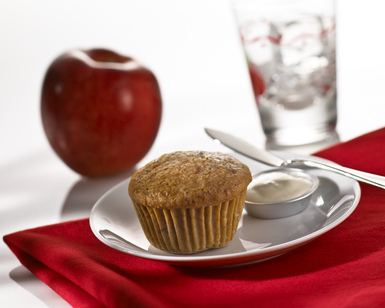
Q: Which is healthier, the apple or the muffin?
A: The apple is healthier than the muffin.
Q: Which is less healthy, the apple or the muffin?
A: The muffin is less healthy than the apple.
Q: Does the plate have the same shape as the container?
A: Yes, both the plate and the container are round.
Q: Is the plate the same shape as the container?
A: Yes, both the plate and the container are round.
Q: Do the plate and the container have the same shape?
A: Yes, both the plate and the container are round.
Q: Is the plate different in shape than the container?
A: No, both the plate and the container are round.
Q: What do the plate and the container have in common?
A: The shape, both the plate and the container are round.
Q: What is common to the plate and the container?
A: The shape, both the plate and the container are round.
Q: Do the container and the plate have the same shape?
A: Yes, both the container and the plate are round.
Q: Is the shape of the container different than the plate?
A: No, both the container and the plate are round.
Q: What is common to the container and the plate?
A: The shape, both the container and the plate are round.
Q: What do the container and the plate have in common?
A: The shape, both the container and the plate are round.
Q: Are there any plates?
A: Yes, there is a plate.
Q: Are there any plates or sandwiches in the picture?
A: Yes, there is a plate.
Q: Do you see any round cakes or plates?
A: Yes, there is a round plate.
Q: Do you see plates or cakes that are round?
A: Yes, the plate is round.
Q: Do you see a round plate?
A: Yes, there is a round plate.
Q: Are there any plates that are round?
A: Yes, there is a plate that is round.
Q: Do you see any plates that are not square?
A: Yes, there is a round plate.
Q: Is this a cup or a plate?
A: This is a plate.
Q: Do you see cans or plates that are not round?
A: No, there is a plate but it is round.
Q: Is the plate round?
A: Yes, the plate is round.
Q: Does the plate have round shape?
A: Yes, the plate is round.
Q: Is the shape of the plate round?
A: Yes, the plate is round.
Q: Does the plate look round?
A: Yes, the plate is round.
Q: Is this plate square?
A: No, the plate is round.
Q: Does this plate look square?
A: No, the plate is round.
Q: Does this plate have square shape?
A: No, the plate is round.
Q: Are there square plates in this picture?
A: No, there is a plate but it is round.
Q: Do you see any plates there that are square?
A: No, there is a plate but it is round.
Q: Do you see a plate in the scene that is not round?
A: No, there is a plate but it is round.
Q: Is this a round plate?
A: Yes, this is a round plate.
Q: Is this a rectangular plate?
A: No, this is a round plate.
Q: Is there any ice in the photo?
A: Yes, there is ice.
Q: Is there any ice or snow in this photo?
A: Yes, there is ice.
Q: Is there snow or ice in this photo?
A: Yes, there is ice.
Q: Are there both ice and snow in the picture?
A: No, there is ice but no snow.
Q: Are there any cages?
A: No, there are no cages.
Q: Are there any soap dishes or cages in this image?
A: No, there are no cages or soap dishes.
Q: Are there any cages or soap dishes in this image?
A: No, there are no cages or soap dishes.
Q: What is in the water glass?
A: The ice is in the water glass.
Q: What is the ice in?
A: The ice is in the water glass.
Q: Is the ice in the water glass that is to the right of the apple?
A: Yes, the ice is in the water glass.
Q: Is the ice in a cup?
A: No, the ice is in the water glass.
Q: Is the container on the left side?
A: No, the container is on the right of the image.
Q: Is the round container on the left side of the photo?
A: No, the container is on the right of the image.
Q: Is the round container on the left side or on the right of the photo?
A: The container is on the right of the image.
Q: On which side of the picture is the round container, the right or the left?
A: The container is on the right of the image.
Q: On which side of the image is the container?
A: The container is on the right of the image.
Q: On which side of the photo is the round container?
A: The container is on the right of the image.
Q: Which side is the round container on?
A: The container is on the right of the image.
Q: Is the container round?
A: Yes, the container is round.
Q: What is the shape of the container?
A: The container is round.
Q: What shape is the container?
A: The container is round.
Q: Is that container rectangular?
A: No, the container is round.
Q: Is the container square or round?
A: The container is round.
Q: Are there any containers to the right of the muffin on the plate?
A: Yes, there is a container to the right of the muffin.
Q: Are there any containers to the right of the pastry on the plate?
A: Yes, there is a container to the right of the muffin.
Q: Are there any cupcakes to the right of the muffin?
A: No, there is a container to the right of the muffin.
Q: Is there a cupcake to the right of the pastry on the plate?
A: No, there is a container to the right of the muffin.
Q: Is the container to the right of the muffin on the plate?
A: Yes, the container is to the right of the muffin.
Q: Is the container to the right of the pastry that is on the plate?
A: Yes, the container is to the right of the muffin.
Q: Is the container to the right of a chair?
A: No, the container is to the right of the muffin.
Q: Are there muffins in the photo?
A: Yes, there is a muffin.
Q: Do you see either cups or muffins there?
A: Yes, there is a muffin.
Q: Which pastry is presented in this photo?
A: The pastry is a muffin.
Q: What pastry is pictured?
A: The pastry is a muffin.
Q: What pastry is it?
A: The pastry is a muffin.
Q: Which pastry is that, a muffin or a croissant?
A: This is a muffin.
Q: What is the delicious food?
A: The food is a muffin.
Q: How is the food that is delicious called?
A: The food is a muffin.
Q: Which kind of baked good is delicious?
A: The baked good is a muffin.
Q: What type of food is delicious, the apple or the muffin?
A: The muffin is delicious.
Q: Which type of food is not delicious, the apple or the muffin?
A: The apple is not delicious.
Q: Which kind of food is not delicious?
A: The food is an apple.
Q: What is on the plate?
A: The muffin is on the plate.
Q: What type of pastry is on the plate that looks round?
A: The pastry is a muffin.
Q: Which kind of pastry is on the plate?
A: The pastry is a muffin.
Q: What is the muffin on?
A: The muffin is on the plate.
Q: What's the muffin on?
A: The muffin is on the plate.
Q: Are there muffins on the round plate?
A: Yes, there is a muffin on the plate.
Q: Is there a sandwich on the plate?
A: No, there is a muffin on the plate.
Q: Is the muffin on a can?
A: No, the muffin is on the plate.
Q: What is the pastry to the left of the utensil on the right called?
A: The pastry is a muffin.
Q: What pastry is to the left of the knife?
A: The pastry is a muffin.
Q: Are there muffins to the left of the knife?
A: Yes, there is a muffin to the left of the knife.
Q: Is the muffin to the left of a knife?
A: Yes, the muffin is to the left of a knife.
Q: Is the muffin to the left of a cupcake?
A: No, the muffin is to the left of a knife.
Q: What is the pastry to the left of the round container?
A: The pastry is a muffin.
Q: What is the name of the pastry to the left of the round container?
A: The pastry is a muffin.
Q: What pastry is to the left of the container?
A: The pastry is a muffin.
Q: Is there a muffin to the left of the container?
A: Yes, there is a muffin to the left of the container.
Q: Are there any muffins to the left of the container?
A: Yes, there is a muffin to the left of the container.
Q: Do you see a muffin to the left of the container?
A: Yes, there is a muffin to the left of the container.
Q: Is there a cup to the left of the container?
A: No, there is a muffin to the left of the container.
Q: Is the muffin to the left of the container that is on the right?
A: Yes, the muffin is to the left of the container.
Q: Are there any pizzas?
A: No, there are no pizzas.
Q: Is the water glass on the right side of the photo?
A: Yes, the water glass is on the right of the image.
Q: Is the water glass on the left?
A: No, the water glass is on the right of the image.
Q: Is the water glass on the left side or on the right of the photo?
A: The water glass is on the right of the image.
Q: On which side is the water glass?
A: The water glass is on the right of the image.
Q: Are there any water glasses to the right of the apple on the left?
A: Yes, there is a water glass to the right of the apple.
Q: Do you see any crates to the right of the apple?
A: No, there is a water glass to the right of the apple.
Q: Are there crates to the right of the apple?
A: No, there is a water glass to the right of the apple.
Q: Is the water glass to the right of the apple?
A: Yes, the water glass is to the right of the apple.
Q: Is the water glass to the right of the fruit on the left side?
A: Yes, the water glass is to the right of the apple.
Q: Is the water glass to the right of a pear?
A: No, the water glass is to the right of the apple.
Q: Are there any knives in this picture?
A: Yes, there is a knife.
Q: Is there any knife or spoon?
A: Yes, there is a knife.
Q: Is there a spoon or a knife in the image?
A: Yes, there is a knife.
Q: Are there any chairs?
A: No, there are no chairs.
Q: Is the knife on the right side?
A: Yes, the knife is on the right of the image.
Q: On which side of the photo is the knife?
A: The knife is on the right of the image.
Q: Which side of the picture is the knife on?
A: The knife is on the right of the image.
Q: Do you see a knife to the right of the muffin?
A: Yes, there is a knife to the right of the muffin.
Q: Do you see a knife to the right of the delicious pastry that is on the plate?
A: Yes, there is a knife to the right of the muffin.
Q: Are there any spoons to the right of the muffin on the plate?
A: No, there is a knife to the right of the muffin.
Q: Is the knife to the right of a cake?
A: No, the knife is to the right of the muffin.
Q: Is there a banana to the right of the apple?
A: No, there is a knife to the right of the apple.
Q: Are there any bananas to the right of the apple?
A: No, there is a knife to the right of the apple.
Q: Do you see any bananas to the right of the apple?
A: No, there is a knife to the right of the apple.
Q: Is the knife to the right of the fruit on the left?
A: Yes, the knife is to the right of the apple.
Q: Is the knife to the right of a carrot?
A: No, the knife is to the right of the apple.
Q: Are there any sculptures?
A: No, there are no sculptures.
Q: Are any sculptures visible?
A: No, there are no sculptures.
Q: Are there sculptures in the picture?
A: No, there are no sculptures.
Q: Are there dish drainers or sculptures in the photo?
A: No, there are no sculptures or dish drainers.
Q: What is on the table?
A: The napkin is on the table.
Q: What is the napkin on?
A: The napkin is on the table.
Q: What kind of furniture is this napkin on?
A: The napkin is on the table.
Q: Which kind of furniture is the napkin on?
A: The napkin is on the table.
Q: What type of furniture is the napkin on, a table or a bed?
A: The napkin is on a table.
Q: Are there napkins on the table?
A: Yes, there is a napkin on the table.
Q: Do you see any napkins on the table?
A: Yes, there is a napkin on the table.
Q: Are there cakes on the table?
A: No, there is a napkin on the table.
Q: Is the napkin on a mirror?
A: No, the napkin is on the table.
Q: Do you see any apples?
A: Yes, there is an apple.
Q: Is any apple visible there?
A: Yes, there is an apple.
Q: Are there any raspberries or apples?
A: Yes, there is an apple.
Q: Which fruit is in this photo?
A: The fruit is an apple.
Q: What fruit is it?
A: The fruit is an apple.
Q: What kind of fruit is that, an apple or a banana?
A: That is an apple.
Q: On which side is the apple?
A: The apple is on the left of the image.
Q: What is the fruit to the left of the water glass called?
A: The fruit is an apple.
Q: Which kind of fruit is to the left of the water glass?
A: The fruit is an apple.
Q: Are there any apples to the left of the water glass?
A: Yes, there is an apple to the left of the water glass.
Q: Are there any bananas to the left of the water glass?
A: No, there is an apple to the left of the water glass.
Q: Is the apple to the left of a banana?
A: No, the apple is to the left of the water glass.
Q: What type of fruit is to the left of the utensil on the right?
A: The fruit is an apple.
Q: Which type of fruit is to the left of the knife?
A: The fruit is an apple.